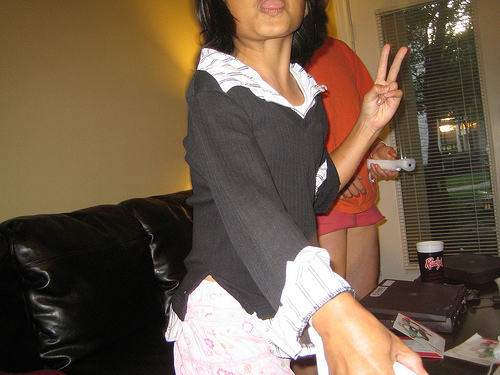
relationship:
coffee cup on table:
[408, 238, 448, 283] [348, 261, 498, 373]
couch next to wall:
[7, 182, 171, 372] [1, 0, 336, 219]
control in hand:
[366, 154, 415, 170] [372, 144, 399, 181]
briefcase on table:
[356, 278, 471, 333] [355, 280, 498, 374]